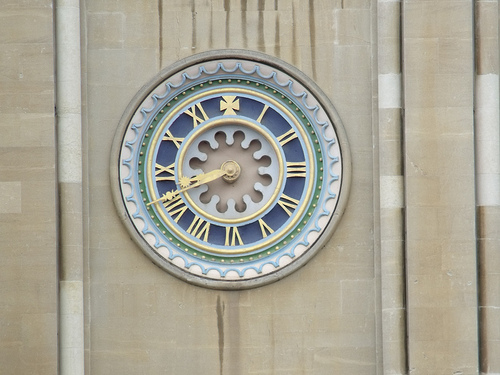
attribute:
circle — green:
[104, 45, 355, 291]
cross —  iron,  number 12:
[218, 92, 240, 117]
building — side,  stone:
[5, 3, 499, 373]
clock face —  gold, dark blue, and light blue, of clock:
[134, 75, 326, 268]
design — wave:
[118, 60, 341, 278]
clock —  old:
[106, 42, 356, 292]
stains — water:
[153, 0, 330, 86]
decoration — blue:
[123, 59, 345, 278]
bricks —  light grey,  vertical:
[54, 0, 86, 374]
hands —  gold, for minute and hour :
[143, 171, 223, 206]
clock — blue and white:
[100, 58, 368, 290]